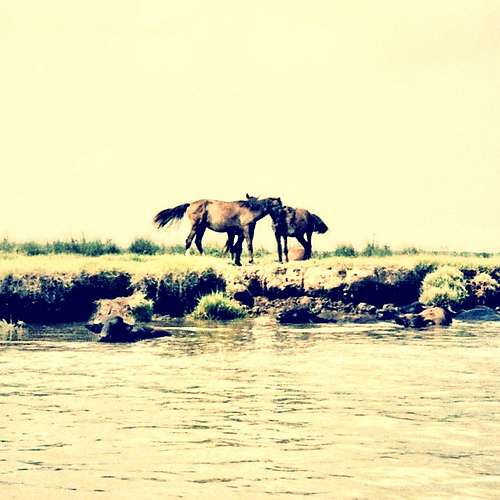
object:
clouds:
[130, 58, 252, 147]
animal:
[83, 315, 171, 342]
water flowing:
[135, 332, 430, 413]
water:
[107, 412, 194, 498]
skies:
[0, 0, 499, 256]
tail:
[154, 204, 189, 229]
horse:
[153, 198, 283, 267]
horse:
[273, 204, 331, 260]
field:
[2, 235, 499, 291]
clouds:
[267, 36, 477, 159]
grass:
[420, 265, 462, 309]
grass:
[196, 290, 243, 322]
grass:
[0, 240, 80, 277]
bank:
[0, 243, 500, 333]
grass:
[127, 239, 195, 274]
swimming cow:
[274, 305, 336, 325]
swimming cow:
[395, 303, 458, 328]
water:
[0, 422, 108, 494]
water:
[281, 436, 380, 498]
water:
[240, 339, 369, 393]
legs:
[239, 217, 254, 267]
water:
[391, 433, 499, 498]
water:
[382, 325, 500, 403]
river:
[0, 315, 499, 499]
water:
[6, 301, 89, 414]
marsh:
[0, 269, 499, 347]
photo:
[0, 0, 499, 498]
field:
[1, 238, 499, 302]